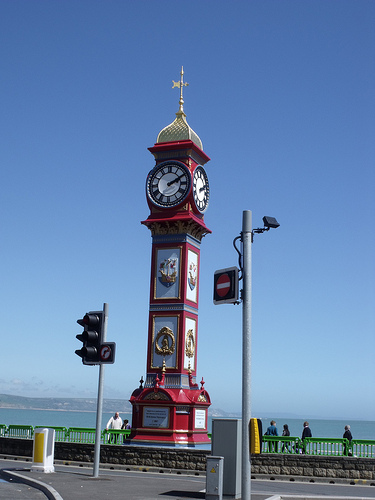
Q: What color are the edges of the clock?
A: Red.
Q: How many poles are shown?
A: Two.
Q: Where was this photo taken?
A: The ocean.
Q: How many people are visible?
A: Seven.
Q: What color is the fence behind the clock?
A: Green.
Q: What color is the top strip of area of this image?
A: Dark blue.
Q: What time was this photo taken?
A: 2:10.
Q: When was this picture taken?
A: Day time.